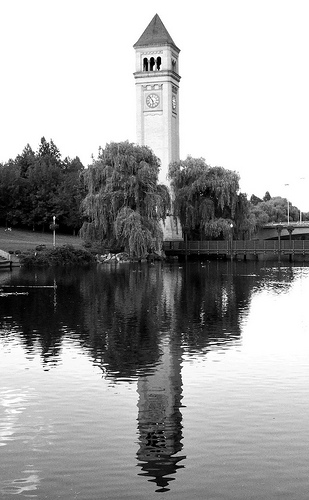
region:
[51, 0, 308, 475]
the picture is in black and white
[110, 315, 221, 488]
the building's reflection is in the water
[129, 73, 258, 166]
the building has a clock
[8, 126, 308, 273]
trees are surrounding the building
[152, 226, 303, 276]
a bridge is over the water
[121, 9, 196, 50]
the building's roof is black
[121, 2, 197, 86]
the roof is in shape of pyramid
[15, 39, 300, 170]
no clouds are in the sky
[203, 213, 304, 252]
lights are on the bridge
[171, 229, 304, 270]
the bridge is brown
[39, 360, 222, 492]
A body of water with a bell tower reflecting in it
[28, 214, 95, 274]
A lamp light post next to some shurbs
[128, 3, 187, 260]
A white clock bell tower next to some trees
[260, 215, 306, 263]
A freeway and some lights and trees in the background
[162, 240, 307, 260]
a walking bridge that goes across the water.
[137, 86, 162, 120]
The white clock tower says 5 minutes until 6 o'clock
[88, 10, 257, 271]
A white clock bell tower surrounded by weaping willow trees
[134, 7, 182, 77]
The tip of the white clock bell tower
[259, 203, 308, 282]
Many cars driving on the freeway bridge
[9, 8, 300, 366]
A clock tower and many trees shadows are in the water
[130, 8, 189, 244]
Clock tower is majestic.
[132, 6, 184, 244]
The clock tower is impressive.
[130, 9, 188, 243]
Clock tower is tall.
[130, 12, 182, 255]
Clock tower is striking.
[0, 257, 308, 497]
The pond is tranquil.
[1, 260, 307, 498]
The pond water is serene.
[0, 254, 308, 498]
The water is sedate.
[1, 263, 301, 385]
The trees shadow appears on the water.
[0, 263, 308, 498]
The pond is very still.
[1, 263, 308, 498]
The water is untroubled.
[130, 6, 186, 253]
a white clocktower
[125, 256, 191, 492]
reflection of a clock tower in water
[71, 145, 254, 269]
two large trees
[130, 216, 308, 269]
a bridge over water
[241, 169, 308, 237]
a driving bridge behind walking bridge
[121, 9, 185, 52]
pointed pyramidal roof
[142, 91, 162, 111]
a round clock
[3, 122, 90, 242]
trees near a body of water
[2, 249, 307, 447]
a lake or pond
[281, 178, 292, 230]
a streetlight on a bridge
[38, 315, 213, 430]
Medium section of river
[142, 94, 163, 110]
Clock on the clock tower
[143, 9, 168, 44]
Top of clock tower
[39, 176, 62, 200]
Mid-section of the trees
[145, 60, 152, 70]
Pillars of the clock tower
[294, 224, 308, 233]
Small section of the bridge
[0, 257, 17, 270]
Small wooden fence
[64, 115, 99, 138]
Small section of the sky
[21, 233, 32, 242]
Small patch of grass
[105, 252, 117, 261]
Gigantic rocks on the bottom of the tree